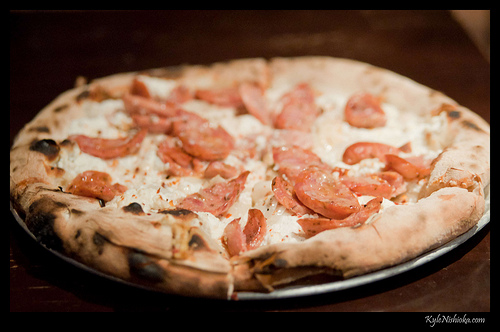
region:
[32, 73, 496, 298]
pizza with cheese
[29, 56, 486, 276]
pizza with pepperoni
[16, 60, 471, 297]
The pizza is on a dish.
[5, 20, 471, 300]
The pizza is cooked properly.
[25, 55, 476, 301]
The pizza has lots of pepperonis on it.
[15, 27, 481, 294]
the pizza has a few burnt spots.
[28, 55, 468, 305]
the pizza is cut in slices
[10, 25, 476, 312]
The pizza is on a table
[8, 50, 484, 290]
the pizza is ready to eat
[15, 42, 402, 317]
The pizza only has one topping.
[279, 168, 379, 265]
pizza with cheese and sausage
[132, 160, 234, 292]
pizza with cheese and sausage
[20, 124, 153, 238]
pizza with cheese and sausage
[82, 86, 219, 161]
pizza with cheese and sausage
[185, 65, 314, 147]
pizza with cheese and sausage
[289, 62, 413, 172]
pizza with cheese and sausage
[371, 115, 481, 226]
pizza with cheese and sausage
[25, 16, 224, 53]
dark brown wooden table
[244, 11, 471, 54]
dark brown wooden table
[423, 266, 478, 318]
dark brown wooden table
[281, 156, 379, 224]
a piece of sausage on the pizaa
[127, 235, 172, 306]
a piece of burnt crust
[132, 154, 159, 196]
cheese on the pizza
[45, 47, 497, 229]
a ver delicious pizza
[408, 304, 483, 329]
the photogrpahers name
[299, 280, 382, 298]
edge of the white plate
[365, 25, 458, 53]
brown wooden table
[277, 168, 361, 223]
two pieces of meat on top of each other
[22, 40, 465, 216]
a round pizza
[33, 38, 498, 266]
a personal pizza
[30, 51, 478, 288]
pepperoni pizza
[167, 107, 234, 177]
pepperoni's in the center of pizza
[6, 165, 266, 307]
crust on the left side of pizza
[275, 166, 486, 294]
crust on right side of pizza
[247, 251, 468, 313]
silver plate pizza is on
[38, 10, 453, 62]
brown table pizza is on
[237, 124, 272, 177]
cheese in center of pizza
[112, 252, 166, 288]
burnt bit on crust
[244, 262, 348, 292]
bubble in crust on front of crust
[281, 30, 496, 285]
right side of pizza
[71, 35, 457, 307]
pizza on the table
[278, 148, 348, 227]
red toppings on the pizza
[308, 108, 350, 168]
white cheese under pizza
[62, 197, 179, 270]
white bread on pizza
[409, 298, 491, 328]
website on bottom left corner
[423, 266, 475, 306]
brown table under pizza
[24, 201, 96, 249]
burned crust of pizza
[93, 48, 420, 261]
many pieces of pizza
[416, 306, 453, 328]
name on bottom left corner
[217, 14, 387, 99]
blurry background of photo